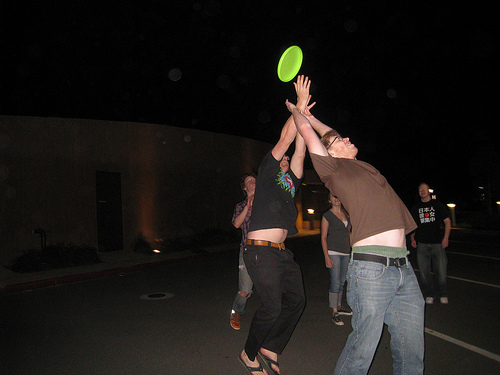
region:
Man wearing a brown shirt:
[298, 111, 441, 373]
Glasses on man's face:
[323, 130, 343, 152]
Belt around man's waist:
[346, 246, 418, 276]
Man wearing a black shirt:
[405, 179, 464, 311]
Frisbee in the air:
[267, 47, 304, 87]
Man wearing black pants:
[242, 127, 306, 374]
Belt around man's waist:
[246, 230, 288, 259]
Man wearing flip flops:
[234, 342, 291, 373]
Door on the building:
[77, 157, 141, 266]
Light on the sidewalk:
[141, 232, 166, 262]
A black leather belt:
[349, 247, 413, 268]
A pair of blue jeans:
[332, 250, 429, 372]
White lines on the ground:
[421, 233, 498, 367]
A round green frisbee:
[275, 41, 305, 85]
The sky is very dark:
[1, 0, 498, 169]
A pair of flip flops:
[237, 342, 283, 373]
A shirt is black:
[243, 144, 307, 242]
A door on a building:
[89, 162, 130, 258]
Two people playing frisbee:
[241, 40, 430, 372]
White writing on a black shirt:
[412, 201, 439, 227]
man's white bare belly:
[368, 230, 413, 240]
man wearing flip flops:
[251, 350, 291, 369]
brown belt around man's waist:
[239, 233, 304, 247]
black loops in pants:
[243, 235, 294, 250]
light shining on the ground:
[141, 236, 171, 253]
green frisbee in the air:
[258, 40, 320, 85]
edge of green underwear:
[346, 235, 422, 264]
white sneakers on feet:
[421, 293, 450, 309]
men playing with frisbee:
[218, 45, 465, 364]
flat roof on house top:
[51, 105, 201, 151]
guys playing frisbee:
[158, 37, 408, 369]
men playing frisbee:
[167, 97, 438, 370]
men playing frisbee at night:
[169, 80, 481, 373]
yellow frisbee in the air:
[275, 45, 310, 85]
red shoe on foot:
[232, 312, 239, 328]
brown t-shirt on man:
[312, 160, 414, 245]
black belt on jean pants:
[352, 252, 417, 264]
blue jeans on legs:
[347, 262, 427, 372]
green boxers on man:
[362, 243, 402, 256]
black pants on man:
[247, 243, 299, 355]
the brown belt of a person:
[244, 236, 286, 249]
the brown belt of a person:
[352, 253, 417, 269]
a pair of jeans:
[242, 237, 304, 357]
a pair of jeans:
[340, 250, 430, 367]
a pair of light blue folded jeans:
[327, 253, 348, 305]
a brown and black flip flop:
[239, 346, 259, 373]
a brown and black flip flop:
[259, 347, 281, 372]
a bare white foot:
[239, 348, 264, 373]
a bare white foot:
[259, 345, 279, 372]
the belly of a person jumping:
[247, 228, 289, 243]